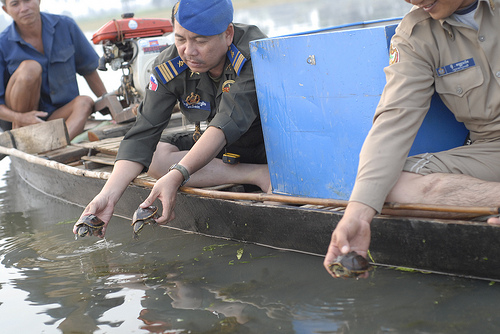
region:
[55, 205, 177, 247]
the man has two turtles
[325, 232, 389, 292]
the other man is holding a turtle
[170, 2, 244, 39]
the man is wearing a blue beret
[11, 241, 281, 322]
the water is gray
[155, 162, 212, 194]
the man is wearing a watch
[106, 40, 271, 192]
the man is wearing an olive colored uniform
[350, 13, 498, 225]
the man is wearing a khaki colored uniform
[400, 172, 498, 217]
the man's hairy leg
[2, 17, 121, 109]
the man is wearing a blue shirt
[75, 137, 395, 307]
the men are putting the turtles into the water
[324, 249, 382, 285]
a small turtle being held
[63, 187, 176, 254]
two small turtles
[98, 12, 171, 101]
a red boat motor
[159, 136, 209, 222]
a silver wrist watch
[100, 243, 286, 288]
green vegetation in the water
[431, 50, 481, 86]
id on a military uniform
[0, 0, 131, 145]
man driving boat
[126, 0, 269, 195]
a soldier in a blue hat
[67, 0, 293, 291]
a soldier releasing two turtles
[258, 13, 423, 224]
a large blue box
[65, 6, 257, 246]
man with blue hat on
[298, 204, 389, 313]
turtle in man's hand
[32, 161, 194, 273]
two turtles in man's hands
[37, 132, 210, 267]
person reaching into water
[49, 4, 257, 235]
person looking down at water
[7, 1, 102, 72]
person wearing blue shirt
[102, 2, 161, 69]
red engine next to man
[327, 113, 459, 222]
brown clothing on man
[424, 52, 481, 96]
blue name tag on shirt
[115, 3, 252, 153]
man looking at turtles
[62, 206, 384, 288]
three brown turtles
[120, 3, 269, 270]
man holding turtle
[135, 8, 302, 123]
man wearing blue hat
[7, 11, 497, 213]
three man sitting down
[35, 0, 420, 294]
three man on a boat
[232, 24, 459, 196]
a big blue box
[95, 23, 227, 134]
an old boat engine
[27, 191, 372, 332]
dirty murky water in background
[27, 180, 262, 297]
turtles going into the water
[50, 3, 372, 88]
clear bright sky in background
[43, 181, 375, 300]
three baby turtles being released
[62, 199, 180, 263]
turtles ready to get in water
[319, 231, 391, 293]
man holding baby turtle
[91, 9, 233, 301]
man holding two turtles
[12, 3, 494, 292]
three men on boat with turtles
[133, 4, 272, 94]
uniformed man with blue hat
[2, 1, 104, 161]
man wearing blue shirt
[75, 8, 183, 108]
engine for small boat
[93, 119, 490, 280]
men with pant legs rolled up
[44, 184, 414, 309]
baby turtles about to be free